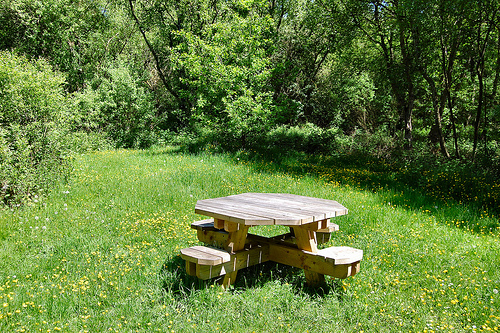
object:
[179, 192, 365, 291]
table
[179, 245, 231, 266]
chair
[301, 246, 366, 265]
chair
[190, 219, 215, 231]
chair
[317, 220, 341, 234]
chair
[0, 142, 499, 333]
grass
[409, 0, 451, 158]
tree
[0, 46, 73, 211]
bush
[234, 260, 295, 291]
shadow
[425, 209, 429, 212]
flower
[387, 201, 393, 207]
flower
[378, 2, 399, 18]
branch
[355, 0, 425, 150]
tree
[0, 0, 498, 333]
photo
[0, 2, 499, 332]
daytime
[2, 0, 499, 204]
background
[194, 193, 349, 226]
top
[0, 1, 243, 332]
left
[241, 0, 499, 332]
right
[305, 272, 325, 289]
leg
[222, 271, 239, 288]
leg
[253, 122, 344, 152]
brush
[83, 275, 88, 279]
flower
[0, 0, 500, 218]
forest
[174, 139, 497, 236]
shadow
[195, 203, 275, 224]
board